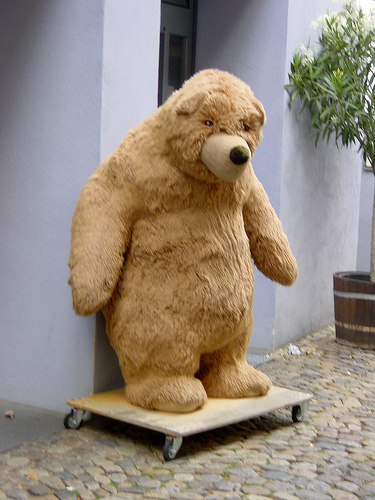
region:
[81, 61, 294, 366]
brown teddy bear statue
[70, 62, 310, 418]
This is a tedbear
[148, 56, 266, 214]
teddy bear is upset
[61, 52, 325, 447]
giant upset looking teddy bear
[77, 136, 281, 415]
a large stuffed bear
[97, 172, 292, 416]
a large teddy bear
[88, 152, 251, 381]
a large stuffed teddy bear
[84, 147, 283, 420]
a large brown bear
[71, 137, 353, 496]
a large stuffed brown bear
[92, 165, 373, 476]
a bear on a wheely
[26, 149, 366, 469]
a bear that is standing up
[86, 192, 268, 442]
a stuffed bear that is standing up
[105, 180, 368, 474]
a teddy bear that is standing up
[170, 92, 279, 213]
the head of a teddy bear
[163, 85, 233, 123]
the ear of a teddy bear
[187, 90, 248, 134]
the eye of a teddy bear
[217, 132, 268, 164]
the nose of a teddy bear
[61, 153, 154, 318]
the arm of a teddy bear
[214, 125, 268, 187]
the black nose of a teddy bear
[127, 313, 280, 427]
the legs of a teddy bear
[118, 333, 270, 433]
the feet of a teddy bear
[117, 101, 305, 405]
the body of a teddy bear